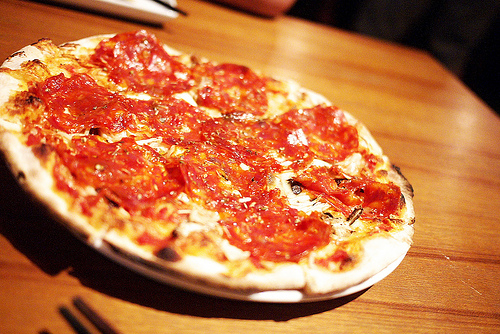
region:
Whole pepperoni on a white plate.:
[2, 31, 414, 301]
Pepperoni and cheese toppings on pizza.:
[39, 34, 406, 250]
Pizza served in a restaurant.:
[1, 0, 498, 331]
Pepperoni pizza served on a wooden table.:
[2, 3, 497, 332]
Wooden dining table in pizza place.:
[2, 0, 499, 330]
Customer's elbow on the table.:
[196, 0, 298, 18]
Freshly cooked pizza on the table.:
[2, 29, 417, 301]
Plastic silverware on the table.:
[37, 293, 126, 332]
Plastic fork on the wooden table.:
[35, 295, 122, 332]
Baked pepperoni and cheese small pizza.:
[0, 27, 415, 302]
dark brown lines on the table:
[435, 240, 483, 273]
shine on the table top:
[410, 75, 485, 141]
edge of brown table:
[396, 32, 456, 77]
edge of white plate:
[122, 0, 188, 27]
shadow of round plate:
[98, 269, 193, 311]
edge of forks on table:
[13, 292, 123, 330]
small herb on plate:
[303, 180, 376, 231]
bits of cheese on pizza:
[220, 178, 282, 218]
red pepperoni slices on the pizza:
[48, 69, 185, 153]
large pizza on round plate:
[10, 35, 439, 308]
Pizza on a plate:
[12, 28, 415, 290]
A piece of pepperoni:
[224, 200, 338, 262]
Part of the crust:
[181, 260, 303, 287]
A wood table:
[298, 26, 387, 81]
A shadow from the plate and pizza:
[6, 235, 84, 257]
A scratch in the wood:
[432, 239, 489, 309]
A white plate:
[234, 291, 305, 306]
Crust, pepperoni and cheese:
[20, 42, 115, 107]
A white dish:
[112, 0, 181, 24]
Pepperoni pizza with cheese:
[9, 30, 419, 295]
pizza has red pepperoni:
[34, 69, 413, 329]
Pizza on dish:
[1, 16, 433, 312]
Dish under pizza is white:
[3, 16, 424, 314]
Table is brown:
[3, 0, 499, 327]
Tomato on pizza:
[33, 27, 403, 264]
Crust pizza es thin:
[8, 21, 429, 306]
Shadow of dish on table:
[8, 218, 180, 322]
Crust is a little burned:
[383, 155, 418, 202]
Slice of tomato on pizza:
[292, 160, 407, 222]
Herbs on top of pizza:
[101, 66, 297, 215]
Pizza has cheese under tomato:
[14, 38, 400, 278]